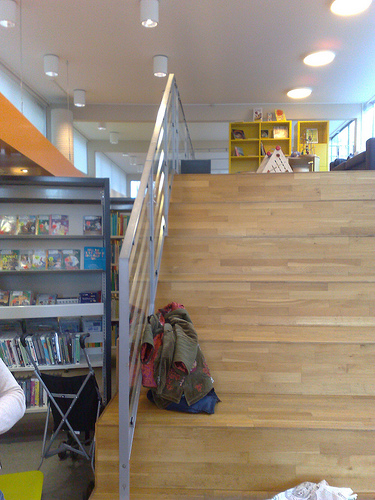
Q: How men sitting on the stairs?
A: Zero.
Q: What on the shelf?
A: Books.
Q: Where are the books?
A: On the shelf.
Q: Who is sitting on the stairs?
A: No one.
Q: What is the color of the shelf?
A: Yellow.